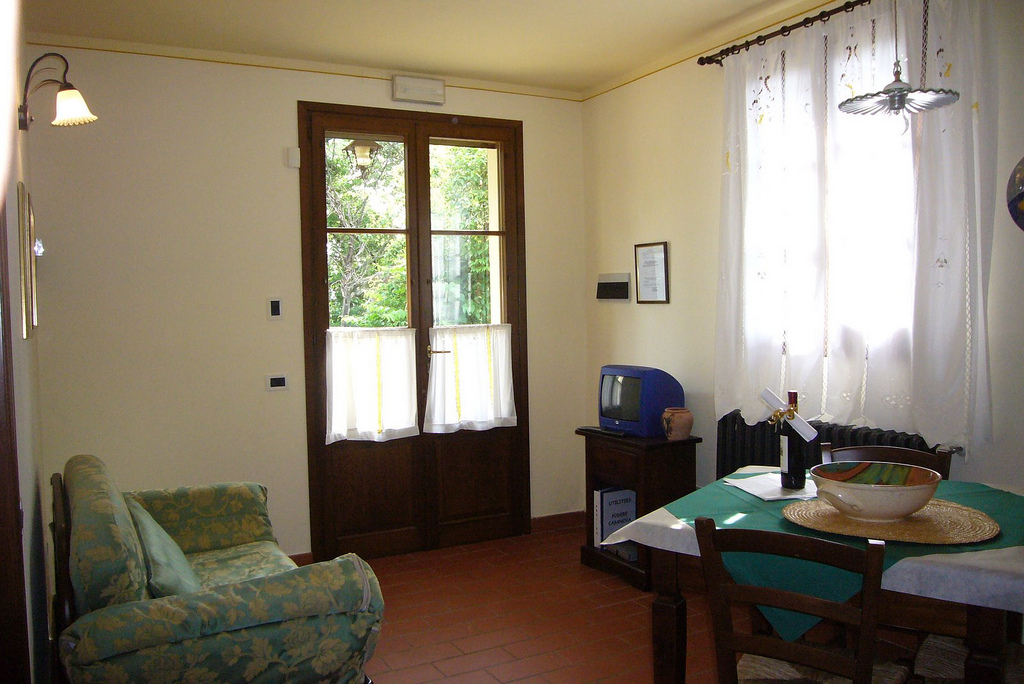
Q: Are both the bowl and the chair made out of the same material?
A: No, the bowl is made of glass and the chair is made of wood.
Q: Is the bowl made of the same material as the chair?
A: No, the bowl is made of glass and the chair is made of wood.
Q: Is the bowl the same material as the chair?
A: No, the bowl is made of glass and the chair is made of wood.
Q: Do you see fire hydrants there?
A: No, there are no fire hydrants.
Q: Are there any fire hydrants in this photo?
A: No, there are no fire hydrants.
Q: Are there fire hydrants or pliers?
A: No, there are no fire hydrants or pliers.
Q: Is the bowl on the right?
A: Yes, the bowl is on the right of the image.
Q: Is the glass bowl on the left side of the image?
A: No, the bowl is on the right of the image.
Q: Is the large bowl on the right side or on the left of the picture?
A: The bowl is on the right of the image.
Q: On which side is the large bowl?
A: The bowl is on the right of the image.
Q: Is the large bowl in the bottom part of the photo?
A: Yes, the bowl is in the bottom of the image.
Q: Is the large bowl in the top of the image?
A: No, the bowl is in the bottom of the image.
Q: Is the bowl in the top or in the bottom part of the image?
A: The bowl is in the bottom of the image.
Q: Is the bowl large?
A: Yes, the bowl is large.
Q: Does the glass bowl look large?
A: Yes, the bowl is large.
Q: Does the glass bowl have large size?
A: Yes, the bowl is large.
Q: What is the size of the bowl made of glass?
A: The bowl is large.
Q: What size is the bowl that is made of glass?
A: The bowl is large.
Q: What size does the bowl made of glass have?
A: The bowl has large size.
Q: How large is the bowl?
A: The bowl is large.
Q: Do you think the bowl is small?
A: No, the bowl is large.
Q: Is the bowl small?
A: No, the bowl is large.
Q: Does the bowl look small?
A: No, the bowl is large.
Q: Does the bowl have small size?
A: No, the bowl is large.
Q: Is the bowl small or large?
A: The bowl is large.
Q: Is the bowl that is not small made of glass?
A: Yes, the bowl is made of glass.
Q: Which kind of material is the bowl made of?
A: The bowl is made of glass.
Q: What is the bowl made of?
A: The bowl is made of glass.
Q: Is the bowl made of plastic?
A: No, the bowl is made of glass.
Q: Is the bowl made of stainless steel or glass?
A: The bowl is made of glass.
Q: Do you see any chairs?
A: Yes, there is a chair.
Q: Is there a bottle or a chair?
A: Yes, there is a chair.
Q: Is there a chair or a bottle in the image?
A: Yes, there is a chair.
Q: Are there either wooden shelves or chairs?
A: Yes, there is a wood chair.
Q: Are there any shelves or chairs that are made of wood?
A: Yes, the chair is made of wood.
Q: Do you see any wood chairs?
A: Yes, there is a wood chair.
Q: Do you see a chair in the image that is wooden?
A: Yes, there is a chair that is wooden.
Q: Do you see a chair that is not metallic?
A: Yes, there is a wooden chair.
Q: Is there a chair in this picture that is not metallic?
A: Yes, there is a wooden chair.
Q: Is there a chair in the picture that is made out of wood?
A: Yes, there is a chair that is made of wood.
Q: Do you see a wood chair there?
A: Yes, there is a chair that is made of wood.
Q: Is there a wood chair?
A: Yes, there is a chair that is made of wood.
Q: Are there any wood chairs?
A: Yes, there is a chair that is made of wood.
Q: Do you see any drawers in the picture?
A: No, there are no drawers.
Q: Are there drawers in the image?
A: No, there are no drawers.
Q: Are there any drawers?
A: No, there are no drawers.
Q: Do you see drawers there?
A: No, there are no drawers.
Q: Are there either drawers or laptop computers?
A: No, there are no drawers or laptop computers.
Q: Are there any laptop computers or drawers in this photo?
A: No, there are no drawers or laptop computers.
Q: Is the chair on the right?
A: Yes, the chair is on the right of the image.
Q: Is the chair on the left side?
A: No, the chair is on the right of the image.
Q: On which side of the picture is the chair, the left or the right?
A: The chair is on the right of the image.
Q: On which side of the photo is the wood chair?
A: The chair is on the right of the image.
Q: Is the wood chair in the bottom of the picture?
A: Yes, the chair is in the bottom of the image.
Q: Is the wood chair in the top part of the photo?
A: No, the chair is in the bottom of the image.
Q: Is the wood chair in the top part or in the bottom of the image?
A: The chair is in the bottom of the image.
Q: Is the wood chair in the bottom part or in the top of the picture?
A: The chair is in the bottom of the image.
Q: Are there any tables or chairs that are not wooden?
A: No, there is a chair but it is wooden.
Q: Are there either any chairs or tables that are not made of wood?
A: No, there is a chair but it is made of wood.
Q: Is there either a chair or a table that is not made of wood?
A: No, there is a chair but it is made of wood.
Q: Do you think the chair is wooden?
A: Yes, the chair is wooden.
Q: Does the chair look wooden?
A: Yes, the chair is wooden.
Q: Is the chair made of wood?
A: Yes, the chair is made of wood.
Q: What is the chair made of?
A: The chair is made of wood.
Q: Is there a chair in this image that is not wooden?
A: No, there is a chair but it is wooden.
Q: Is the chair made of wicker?
A: No, the chair is made of wood.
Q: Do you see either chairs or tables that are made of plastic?
A: No, there is a chair but it is made of wood.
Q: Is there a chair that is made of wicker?
A: No, there is a chair but it is made of wood.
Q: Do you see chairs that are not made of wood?
A: No, there is a chair but it is made of wood.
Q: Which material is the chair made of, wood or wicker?
A: The chair is made of wood.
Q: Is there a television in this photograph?
A: Yes, there is a television.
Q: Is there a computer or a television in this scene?
A: Yes, there is a television.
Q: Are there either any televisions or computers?
A: Yes, there is a television.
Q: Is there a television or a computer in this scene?
A: Yes, there is a television.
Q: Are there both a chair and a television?
A: Yes, there are both a television and a chair.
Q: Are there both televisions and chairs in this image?
A: Yes, there are both a television and a chair.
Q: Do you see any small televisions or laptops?
A: Yes, there is a small television.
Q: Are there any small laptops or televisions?
A: Yes, there is a small television.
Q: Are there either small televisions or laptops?
A: Yes, there is a small television.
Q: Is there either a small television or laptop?
A: Yes, there is a small television.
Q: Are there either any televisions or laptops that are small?
A: Yes, the television is small.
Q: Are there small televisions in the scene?
A: Yes, there is a small television.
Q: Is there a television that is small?
A: Yes, there is a television that is small.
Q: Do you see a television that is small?
A: Yes, there is a television that is small.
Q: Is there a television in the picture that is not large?
A: Yes, there is a small television.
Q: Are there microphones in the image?
A: No, there are no microphones.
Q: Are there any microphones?
A: No, there are no microphones.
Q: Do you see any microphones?
A: No, there are no microphones.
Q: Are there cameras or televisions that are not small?
A: No, there is a television but it is small.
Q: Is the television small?
A: Yes, the television is small.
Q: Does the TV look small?
A: Yes, the TV is small.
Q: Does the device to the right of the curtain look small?
A: Yes, the TV is small.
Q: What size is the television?
A: The television is small.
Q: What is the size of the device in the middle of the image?
A: The television is small.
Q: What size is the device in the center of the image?
A: The television is small.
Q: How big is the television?
A: The television is small.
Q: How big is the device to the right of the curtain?
A: The television is small.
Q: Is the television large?
A: No, the television is small.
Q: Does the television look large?
A: No, the television is small.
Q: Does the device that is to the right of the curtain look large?
A: No, the television is small.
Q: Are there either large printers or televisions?
A: No, there is a television but it is small.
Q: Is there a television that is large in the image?
A: No, there is a television but it is small.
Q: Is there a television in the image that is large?
A: No, there is a television but it is small.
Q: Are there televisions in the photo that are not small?
A: No, there is a television but it is small.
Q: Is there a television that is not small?
A: No, there is a television but it is small.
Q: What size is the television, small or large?
A: The television is small.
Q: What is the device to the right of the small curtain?
A: The device is a television.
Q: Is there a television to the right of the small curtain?
A: Yes, there is a television to the right of the curtain.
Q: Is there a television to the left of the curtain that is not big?
A: No, the television is to the right of the curtain.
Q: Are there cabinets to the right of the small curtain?
A: No, there is a television to the right of the curtain.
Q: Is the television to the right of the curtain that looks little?
A: Yes, the television is to the right of the curtain.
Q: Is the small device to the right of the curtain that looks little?
A: Yes, the television is to the right of the curtain.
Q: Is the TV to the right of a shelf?
A: No, the TV is to the right of the curtain.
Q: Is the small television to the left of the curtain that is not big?
A: No, the television is to the right of the curtain.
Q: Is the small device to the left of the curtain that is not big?
A: No, the television is to the right of the curtain.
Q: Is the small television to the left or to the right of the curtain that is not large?
A: The television is to the right of the curtain.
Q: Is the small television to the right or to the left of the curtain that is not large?
A: The television is to the right of the curtain.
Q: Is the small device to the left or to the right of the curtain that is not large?
A: The television is to the right of the curtain.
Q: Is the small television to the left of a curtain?
A: No, the TV is to the right of a curtain.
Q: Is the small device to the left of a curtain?
A: No, the TV is to the right of a curtain.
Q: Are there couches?
A: Yes, there is a couch.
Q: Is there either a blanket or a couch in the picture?
A: Yes, there is a couch.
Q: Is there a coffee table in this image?
A: No, there are no coffee tables.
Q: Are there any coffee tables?
A: No, there are no coffee tables.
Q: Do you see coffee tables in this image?
A: No, there are no coffee tables.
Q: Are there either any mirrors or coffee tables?
A: No, there are no coffee tables or mirrors.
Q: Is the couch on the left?
A: Yes, the couch is on the left of the image.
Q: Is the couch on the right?
A: No, the couch is on the left of the image.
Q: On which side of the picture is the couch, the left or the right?
A: The couch is on the left of the image.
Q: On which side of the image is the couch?
A: The couch is on the left of the image.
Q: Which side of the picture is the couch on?
A: The couch is on the left of the image.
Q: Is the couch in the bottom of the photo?
A: Yes, the couch is in the bottom of the image.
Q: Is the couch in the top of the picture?
A: No, the couch is in the bottom of the image.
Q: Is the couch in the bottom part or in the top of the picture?
A: The couch is in the bottom of the image.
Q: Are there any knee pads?
A: No, there are no knee pads.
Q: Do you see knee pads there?
A: No, there are no knee pads.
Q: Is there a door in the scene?
A: Yes, there is a door.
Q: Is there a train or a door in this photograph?
A: Yes, there is a door.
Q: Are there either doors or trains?
A: Yes, there is a door.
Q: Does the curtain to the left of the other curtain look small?
A: Yes, the curtain is small.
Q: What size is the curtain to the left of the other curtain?
A: The curtain is small.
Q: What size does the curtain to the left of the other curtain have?
A: The curtain has small size.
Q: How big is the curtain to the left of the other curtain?
A: The curtain is small.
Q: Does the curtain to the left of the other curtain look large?
A: No, the curtain is small.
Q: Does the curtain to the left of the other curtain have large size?
A: No, the curtain is small.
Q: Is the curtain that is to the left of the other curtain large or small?
A: The curtain is small.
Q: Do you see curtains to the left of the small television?
A: Yes, there is a curtain to the left of the TV.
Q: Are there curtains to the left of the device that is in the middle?
A: Yes, there is a curtain to the left of the TV.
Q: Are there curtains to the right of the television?
A: No, the curtain is to the left of the television.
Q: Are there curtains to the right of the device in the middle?
A: No, the curtain is to the left of the television.